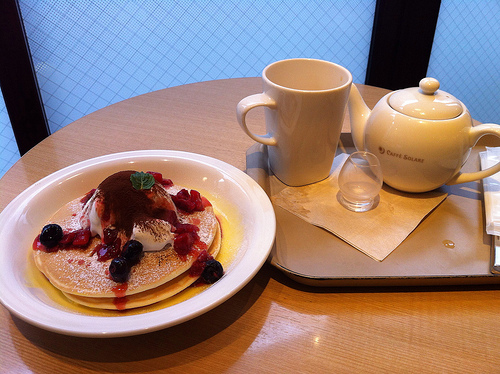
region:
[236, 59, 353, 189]
white cup sitting on a tray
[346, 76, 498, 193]
white teapot sitting on the tray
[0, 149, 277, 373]
white bowel with food in it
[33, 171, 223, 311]
two pancakes with fruit on top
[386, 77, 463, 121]
white top of tea kettle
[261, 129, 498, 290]
light brown tray with items on it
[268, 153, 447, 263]
white napkin lying on the tray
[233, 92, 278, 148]
white cup handle of the cup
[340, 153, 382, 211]
empty glass sitting on the napkin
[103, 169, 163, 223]
fruit on top of the pancakes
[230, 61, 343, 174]
cup on a tray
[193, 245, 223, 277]
berry on a plate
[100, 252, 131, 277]
berry on a plate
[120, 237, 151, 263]
berry on a plate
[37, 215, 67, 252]
berry on a plate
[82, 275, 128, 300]
pancake on a plate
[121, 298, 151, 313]
pancake on a plate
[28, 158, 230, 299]
pancake on a plate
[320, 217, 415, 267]
napkin on a plate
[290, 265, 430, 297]
tray on a table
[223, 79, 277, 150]
handle of a ceramic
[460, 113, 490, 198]
handle of a ceramic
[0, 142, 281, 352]
plate on a table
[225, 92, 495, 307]
plate on a table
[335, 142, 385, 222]
cup on a plate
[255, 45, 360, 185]
cup on a plate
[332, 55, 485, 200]
pot on a plate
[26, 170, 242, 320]
pancakes on a plate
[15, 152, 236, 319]
two pancakes on a plate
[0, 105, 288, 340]
white plate on a table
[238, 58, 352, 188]
A white plain coffee mug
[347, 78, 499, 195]
A round white tea pot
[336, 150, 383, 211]
A small and round clear cup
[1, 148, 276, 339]
A small white dish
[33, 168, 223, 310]
Two pancakes topped with syrup and fruits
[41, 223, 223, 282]
Four blueberries served as part of a breakfast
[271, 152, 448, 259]
A white napkin lying down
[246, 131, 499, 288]
A tan colored serving tray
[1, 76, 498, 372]
A small light colored round table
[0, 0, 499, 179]
A screen with a rhombus shaped design.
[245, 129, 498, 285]
a tray on a table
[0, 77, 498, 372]
a round wood table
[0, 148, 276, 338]
a white plate on a table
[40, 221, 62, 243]
a blackberry on a pancake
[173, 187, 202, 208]
a raspberry on a pancake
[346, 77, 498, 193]
a teapot on a tray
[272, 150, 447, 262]
a square white napkin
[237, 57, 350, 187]
a white mug on a tray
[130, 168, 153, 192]
a green mint leaf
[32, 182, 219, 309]
two pancakes in a plate